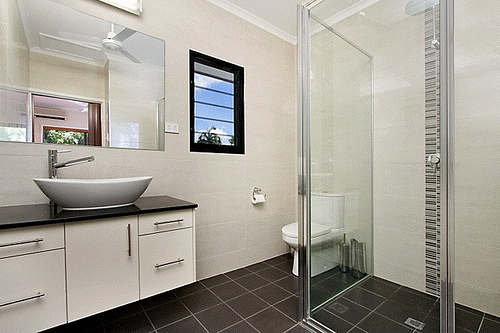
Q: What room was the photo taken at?
A: It was taken at the bathroom.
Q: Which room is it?
A: It is a bathroom.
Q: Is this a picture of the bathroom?
A: Yes, it is showing the bathroom.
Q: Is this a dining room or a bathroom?
A: It is a bathroom.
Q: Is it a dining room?
A: No, it is a bathroom.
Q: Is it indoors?
A: Yes, it is indoors.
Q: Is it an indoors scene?
A: Yes, it is indoors.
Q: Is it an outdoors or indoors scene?
A: It is indoors.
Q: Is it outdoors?
A: No, it is indoors.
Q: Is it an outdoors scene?
A: No, it is indoors.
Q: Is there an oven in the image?
A: No, there are no ovens.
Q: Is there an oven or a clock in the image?
A: No, there are no ovens or clocks.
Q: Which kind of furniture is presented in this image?
A: The furniture is cabinets.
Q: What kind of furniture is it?
A: The pieces of furniture are cabinets.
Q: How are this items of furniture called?
A: These are cabinets.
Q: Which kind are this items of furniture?
A: These are cabinets.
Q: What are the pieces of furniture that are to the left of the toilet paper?
A: The pieces of furniture are cabinets.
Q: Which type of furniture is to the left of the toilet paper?
A: The pieces of furniture are cabinets.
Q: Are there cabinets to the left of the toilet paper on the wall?
A: Yes, there are cabinets to the left of the toilet paper.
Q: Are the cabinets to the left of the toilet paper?
A: Yes, the cabinets are to the left of the toilet paper.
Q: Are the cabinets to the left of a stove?
A: No, the cabinets are to the left of the toilet paper.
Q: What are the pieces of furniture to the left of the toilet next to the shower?
A: The pieces of furniture are cabinets.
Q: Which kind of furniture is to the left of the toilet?
A: The pieces of furniture are cabinets.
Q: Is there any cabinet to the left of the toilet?
A: Yes, there are cabinets to the left of the toilet.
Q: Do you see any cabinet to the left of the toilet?
A: Yes, there are cabinets to the left of the toilet.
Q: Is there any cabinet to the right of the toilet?
A: No, the cabinets are to the left of the toilet.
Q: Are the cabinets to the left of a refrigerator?
A: No, the cabinets are to the left of the toilet.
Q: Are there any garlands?
A: No, there are no garlands.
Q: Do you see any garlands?
A: No, there are no garlands.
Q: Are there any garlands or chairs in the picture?
A: No, there are no garlands or chairs.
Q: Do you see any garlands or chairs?
A: No, there are no garlands or chairs.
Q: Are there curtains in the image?
A: No, there are no curtains.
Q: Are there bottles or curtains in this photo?
A: No, there are no curtains or bottles.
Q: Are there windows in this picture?
A: Yes, there is a window.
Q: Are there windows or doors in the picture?
A: Yes, there is a window.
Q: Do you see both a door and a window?
A: Yes, there are both a window and a door.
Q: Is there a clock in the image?
A: No, there are no clocks.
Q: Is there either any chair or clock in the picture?
A: No, there are no clocks or chairs.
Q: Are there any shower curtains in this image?
A: No, there are no shower curtains.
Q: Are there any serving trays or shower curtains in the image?
A: No, there are no shower curtains or serving trays.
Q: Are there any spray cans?
A: No, there are no spray cans.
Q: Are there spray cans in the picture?
A: No, there are no spray cans.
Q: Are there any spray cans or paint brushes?
A: No, there are no spray cans or paint brushes.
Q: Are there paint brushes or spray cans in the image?
A: No, there are no spray cans or paint brushes.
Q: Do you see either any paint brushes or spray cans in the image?
A: No, there are no spray cans or paint brushes.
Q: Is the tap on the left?
A: Yes, the tap is on the left of the image.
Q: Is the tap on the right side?
A: No, the tap is on the left of the image.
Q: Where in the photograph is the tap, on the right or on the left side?
A: The tap is on the left of the image.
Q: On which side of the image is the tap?
A: The tap is on the left of the image.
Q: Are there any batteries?
A: No, there are no batteries.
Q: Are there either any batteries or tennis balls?
A: No, there are no batteries or tennis balls.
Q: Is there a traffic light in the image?
A: No, there are no traffic lights.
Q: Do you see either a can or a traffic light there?
A: No, there are no traffic lights or cans.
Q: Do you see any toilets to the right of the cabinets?
A: Yes, there is a toilet to the right of the cabinets.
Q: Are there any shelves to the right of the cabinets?
A: No, there is a toilet to the right of the cabinets.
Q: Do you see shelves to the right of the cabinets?
A: No, there is a toilet to the right of the cabinets.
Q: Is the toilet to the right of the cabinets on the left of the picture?
A: Yes, the toilet is to the right of the cabinets.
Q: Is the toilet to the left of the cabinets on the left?
A: No, the toilet is to the right of the cabinets.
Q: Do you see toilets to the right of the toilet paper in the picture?
A: Yes, there is a toilet to the right of the toilet paper.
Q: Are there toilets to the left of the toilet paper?
A: No, the toilet is to the right of the toilet paper.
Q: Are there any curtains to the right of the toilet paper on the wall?
A: No, there is a toilet to the right of the toilet paper.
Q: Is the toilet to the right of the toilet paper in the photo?
A: Yes, the toilet is to the right of the toilet paper.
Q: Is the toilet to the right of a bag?
A: No, the toilet is to the right of the toilet paper.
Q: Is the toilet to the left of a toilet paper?
A: No, the toilet is to the right of a toilet paper.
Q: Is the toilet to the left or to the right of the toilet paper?
A: The toilet is to the right of the toilet paper.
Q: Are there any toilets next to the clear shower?
A: Yes, there is a toilet next to the shower.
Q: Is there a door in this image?
A: Yes, there is a door.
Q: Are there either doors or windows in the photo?
A: Yes, there is a door.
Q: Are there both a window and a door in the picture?
A: Yes, there are both a door and a window.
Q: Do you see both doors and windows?
A: Yes, there are both a door and windows.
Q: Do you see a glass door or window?
A: Yes, there is a glass door.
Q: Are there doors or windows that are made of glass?
A: Yes, the door is made of glass.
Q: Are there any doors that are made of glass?
A: Yes, there is a door that is made of glass.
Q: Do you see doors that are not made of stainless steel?
A: Yes, there is a door that is made of glass.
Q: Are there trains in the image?
A: No, there are no trains.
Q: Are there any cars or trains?
A: No, there are no trains or cars.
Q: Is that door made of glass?
A: Yes, the door is made of glass.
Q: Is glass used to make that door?
A: Yes, the door is made of glass.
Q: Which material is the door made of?
A: The door is made of glass.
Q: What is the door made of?
A: The door is made of glass.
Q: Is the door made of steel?
A: No, the door is made of glass.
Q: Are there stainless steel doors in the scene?
A: No, there is a door but it is made of glass.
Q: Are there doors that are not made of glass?
A: No, there is a door but it is made of glass.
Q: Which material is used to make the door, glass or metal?
A: The door is made of glass.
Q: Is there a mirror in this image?
A: Yes, there is a mirror.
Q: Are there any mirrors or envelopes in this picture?
A: Yes, there is a mirror.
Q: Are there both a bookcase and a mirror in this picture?
A: No, there is a mirror but no bookcases.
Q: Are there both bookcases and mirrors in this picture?
A: No, there is a mirror but no bookcases.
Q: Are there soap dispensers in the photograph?
A: No, there are no soap dispensers.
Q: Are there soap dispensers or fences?
A: No, there are no soap dispensers or fences.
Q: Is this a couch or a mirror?
A: This is a mirror.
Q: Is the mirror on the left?
A: Yes, the mirror is on the left of the image.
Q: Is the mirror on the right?
A: No, the mirror is on the left of the image.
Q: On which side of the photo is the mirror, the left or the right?
A: The mirror is on the left of the image.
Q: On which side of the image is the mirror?
A: The mirror is on the left of the image.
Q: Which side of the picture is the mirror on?
A: The mirror is on the left of the image.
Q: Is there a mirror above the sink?
A: Yes, there is a mirror above the sink.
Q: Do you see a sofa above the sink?
A: No, there is a mirror above the sink.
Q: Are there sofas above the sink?
A: No, there is a mirror above the sink.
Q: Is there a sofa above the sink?
A: No, there is a mirror above the sink.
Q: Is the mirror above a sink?
A: Yes, the mirror is above a sink.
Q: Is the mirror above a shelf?
A: No, the mirror is above a sink.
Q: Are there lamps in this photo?
A: No, there are no lamps.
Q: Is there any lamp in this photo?
A: No, there are no lamps.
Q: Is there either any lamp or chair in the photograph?
A: No, there are no lamps or chairs.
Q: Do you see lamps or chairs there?
A: No, there are no lamps or chairs.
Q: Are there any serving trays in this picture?
A: No, there are no serving trays.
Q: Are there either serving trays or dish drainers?
A: No, there are no serving trays or dish drainers.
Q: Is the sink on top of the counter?
A: Yes, the sink is on top of the counter.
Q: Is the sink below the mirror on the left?
A: Yes, the sink is below the mirror.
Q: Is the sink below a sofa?
A: No, the sink is below the mirror.